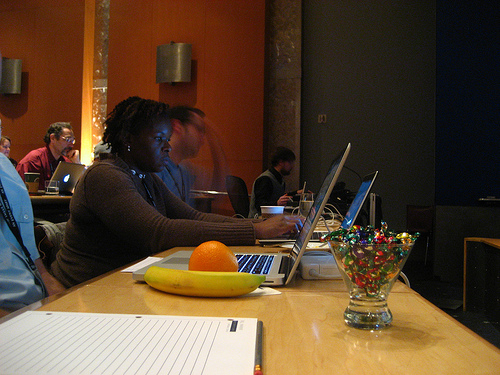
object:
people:
[18, 121, 83, 205]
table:
[0, 236, 500, 373]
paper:
[0, 309, 263, 374]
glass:
[316, 222, 420, 330]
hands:
[252, 212, 308, 239]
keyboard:
[220, 252, 276, 276]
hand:
[63, 148, 80, 162]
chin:
[60, 147, 75, 157]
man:
[246, 141, 311, 221]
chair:
[222, 173, 280, 228]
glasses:
[188, 125, 208, 134]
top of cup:
[258, 204, 285, 214]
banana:
[142, 262, 267, 300]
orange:
[186, 237, 241, 280]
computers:
[130, 140, 354, 289]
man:
[143, 96, 235, 240]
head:
[163, 106, 209, 158]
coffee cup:
[259, 203, 285, 228]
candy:
[393, 228, 413, 239]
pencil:
[251, 319, 266, 375]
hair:
[100, 95, 174, 156]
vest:
[249, 168, 287, 221]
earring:
[125, 143, 135, 155]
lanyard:
[128, 158, 157, 211]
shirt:
[49, 154, 256, 291]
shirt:
[14, 146, 75, 193]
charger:
[300, 252, 340, 282]